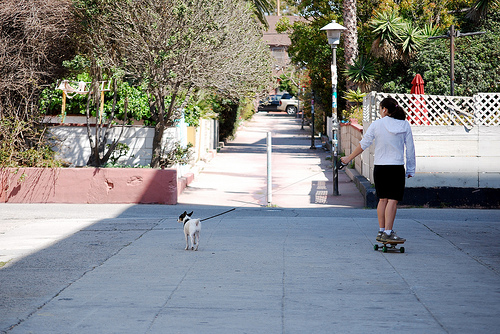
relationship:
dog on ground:
[174, 207, 218, 251] [1, 204, 500, 334]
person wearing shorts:
[340, 97, 417, 243] [373, 163, 405, 199]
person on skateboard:
[334, 97, 419, 243] [359, 223, 426, 270]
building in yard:
[23, 105, 221, 165] [0, 125, 69, 199]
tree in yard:
[87, 0, 277, 126] [0, 115, 187, 171]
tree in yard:
[49, 0, 136, 119] [0, 115, 187, 171]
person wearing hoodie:
[340, 97, 417, 243] [358, 116, 416, 177]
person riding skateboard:
[340, 97, 417, 243] [371, 236, 409, 256]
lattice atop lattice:
[361, 82, 488, 135] [361, 91, 500, 127]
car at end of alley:
[273, 89, 304, 117] [170, 97, 373, 207]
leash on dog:
[201, 154, 345, 223] [175, 205, 206, 253]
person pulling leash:
[340, 97, 417, 243] [201, 154, 345, 223]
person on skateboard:
[340, 97, 417, 243] [372, 234, 406, 253]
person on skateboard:
[340, 97, 417, 243] [369, 231, 414, 256]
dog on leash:
[177, 210, 202, 250] [201, 161, 336, 223]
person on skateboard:
[340, 97, 417, 243] [363, 231, 430, 253]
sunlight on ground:
[184, 127, 355, 210] [205, 137, 370, 209]